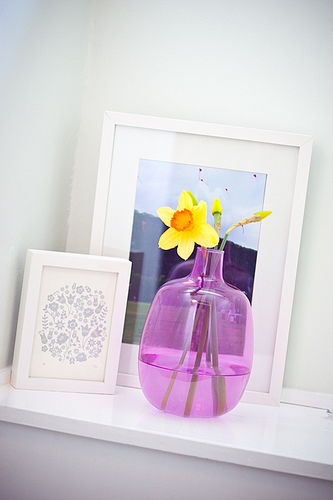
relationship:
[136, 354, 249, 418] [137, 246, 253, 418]
water in jar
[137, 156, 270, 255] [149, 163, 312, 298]
sky in frame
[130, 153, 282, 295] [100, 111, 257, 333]
painting in frame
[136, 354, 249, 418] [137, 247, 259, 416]
water in vase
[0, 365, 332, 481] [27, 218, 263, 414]
mantle holding items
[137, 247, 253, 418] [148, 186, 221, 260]
jar holding flower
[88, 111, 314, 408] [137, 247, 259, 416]
framed picture behind vase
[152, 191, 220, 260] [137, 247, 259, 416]
flower in vase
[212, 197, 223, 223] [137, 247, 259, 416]
flower in vase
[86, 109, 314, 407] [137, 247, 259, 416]
frame behind vase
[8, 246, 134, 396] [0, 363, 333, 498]
items placed on shelf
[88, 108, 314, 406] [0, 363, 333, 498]
items placed on shelf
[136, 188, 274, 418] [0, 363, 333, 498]
items placed on shelf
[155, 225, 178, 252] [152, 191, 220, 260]
petal on flower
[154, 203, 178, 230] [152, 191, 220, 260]
petal on flower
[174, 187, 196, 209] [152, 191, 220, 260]
petal on flower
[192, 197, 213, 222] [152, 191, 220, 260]
petal on flower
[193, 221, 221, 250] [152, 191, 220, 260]
petal on flower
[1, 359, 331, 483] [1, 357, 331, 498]
counter on dresser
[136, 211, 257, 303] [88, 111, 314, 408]
hill in framed picture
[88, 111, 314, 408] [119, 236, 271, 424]
framed picture behind vase